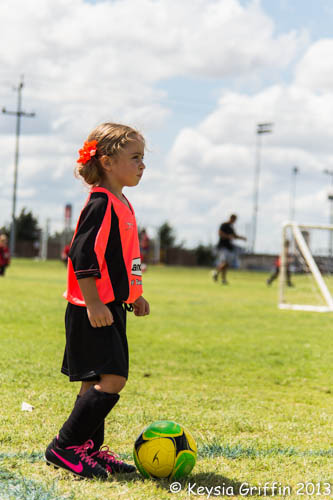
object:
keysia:
[185, 478, 237, 498]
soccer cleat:
[85, 440, 137, 478]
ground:
[138, 292, 262, 437]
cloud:
[297, 40, 331, 96]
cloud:
[48, 1, 141, 54]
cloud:
[27, 62, 116, 109]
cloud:
[170, 177, 218, 207]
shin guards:
[58, 389, 119, 447]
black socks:
[57, 389, 121, 446]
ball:
[133, 421, 196, 482]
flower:
[77, 139, 97, 166]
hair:
[79, 122, 148, 183]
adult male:
[212, 214, 247, 285]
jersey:
[62, 184, 142, 311]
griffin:
[239, 480, 291, 499]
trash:
[20, 401, 35, 413]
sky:
[4, 0, 332, 248]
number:
[294, 482, 333, 498]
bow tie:
[76, 139, 98, 164]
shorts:
[60, 287, 128, 383]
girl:
[44, 121, 151, 483]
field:
[0, 256, 331, 499]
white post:
[280, 226, 286, 303]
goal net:
[281, 222, 332, 314]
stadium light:
[248, 118, 274, 251]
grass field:
[175, 315, 314, 363]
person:
[267, 239, 293, 287]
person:
[0, 233, 10, 275]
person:
[62, 242, 67, 266]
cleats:
[43, 454, 107, 480]